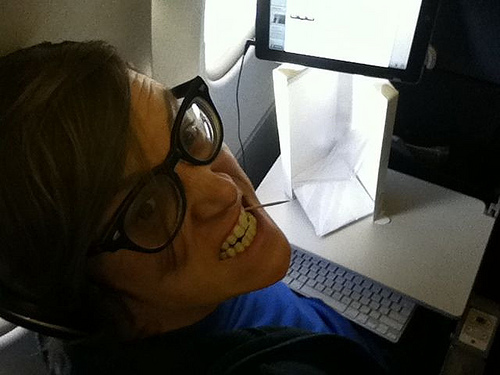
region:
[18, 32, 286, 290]
guy is wearing eyeglasses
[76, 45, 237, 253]
guy is wearing eyeglasses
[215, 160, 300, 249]
a toothpick on person's mouth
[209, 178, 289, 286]
a toothpick on person's mouth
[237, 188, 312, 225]
a tooth pick in mouth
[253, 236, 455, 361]
a gray keyboard on desk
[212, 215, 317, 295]
two rows of teeth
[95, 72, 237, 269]
black glasses on face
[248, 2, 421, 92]
some sort of monitor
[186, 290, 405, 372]
a blue and black shirt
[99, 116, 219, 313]
hair coming across eye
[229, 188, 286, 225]
tooth pick sticking out of mouth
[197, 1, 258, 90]
a window of a plane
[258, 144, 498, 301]
a white table top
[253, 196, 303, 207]
The tooth pick in the persons mouth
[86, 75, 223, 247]
The thick black glasses on the mans face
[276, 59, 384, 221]
The propped up book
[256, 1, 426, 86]
The screen of the tablet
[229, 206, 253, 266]
The persons teeth holding a tooth pick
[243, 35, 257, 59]
The head phone jack attached to the tablet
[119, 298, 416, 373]
The persons blue shirt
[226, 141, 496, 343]
The apple laptop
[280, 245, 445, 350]
The persons white and silver keyboard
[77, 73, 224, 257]
black framed eyeglasses on face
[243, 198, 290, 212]
toothpick sticking out of mouth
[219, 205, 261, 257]
set of white teeth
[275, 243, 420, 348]
white computer keyboard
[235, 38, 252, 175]
black cord hanging down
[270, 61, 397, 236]
white paper bag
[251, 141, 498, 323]
tray sticking out of chair back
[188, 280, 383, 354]
royal blue shirt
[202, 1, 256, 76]
airplane window open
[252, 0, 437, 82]
flat screen turned on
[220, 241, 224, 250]
a yellowish white tooth in a mouth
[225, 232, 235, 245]
a yellowish white tooth in a mouth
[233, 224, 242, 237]
a yellowish white tooth in a mouth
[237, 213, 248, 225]
a yellowish white tooth in a mouth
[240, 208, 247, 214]
a yellowish white tooth in a mouth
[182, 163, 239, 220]
the nose of a face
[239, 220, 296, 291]
the chin of a face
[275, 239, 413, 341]
the grey keyboard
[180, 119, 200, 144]
an eye on a face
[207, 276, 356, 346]
a blue t-shirt